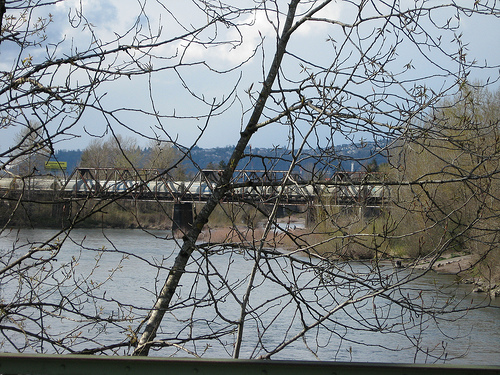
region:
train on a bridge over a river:
[0, 153, 392, 210]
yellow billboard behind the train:
[40, 159, 70, 176]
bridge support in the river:
[170, 201, 200, 236]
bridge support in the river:
[49, 198, 76, 228]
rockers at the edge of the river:
[471, 280, 498, 305]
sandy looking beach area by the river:
[413, 246, 471, 281]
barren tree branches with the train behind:
[11, 23, 358, 359]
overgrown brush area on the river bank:
[386, 96, 498, 291]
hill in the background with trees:
[13, 142, 396, 174]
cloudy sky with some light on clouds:
[1, 1, 488, 148]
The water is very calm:
[37, 213, 150, 321]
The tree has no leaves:
[12, 25, 462, 366]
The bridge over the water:
[18, 155, 410, 233]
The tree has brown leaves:
[374, 89, 498, 254]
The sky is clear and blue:
[19, 6, 232, 138]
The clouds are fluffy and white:
[81, 13, 311, 58]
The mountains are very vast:
[2, 130, 409, 187]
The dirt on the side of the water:
[418, 240, 497, 301]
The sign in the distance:
[31, 145, 82, 177]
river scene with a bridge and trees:
[7, 1, 494, 368]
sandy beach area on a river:
[411, 246, 478, 281]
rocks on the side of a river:
[457, 271, 497, 303]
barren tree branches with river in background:
[14, 1, 391, 341]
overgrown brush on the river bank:
[321, 85, 494, 300]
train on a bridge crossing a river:
[2, 167, 387, 208]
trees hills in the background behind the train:
[13, 142, 398, 181]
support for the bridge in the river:
[49, 196, 77, 227]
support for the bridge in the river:
[169, 199, 198, 236]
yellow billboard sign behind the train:
[44, 158, 67, 175]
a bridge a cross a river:
[5, 170, 212, 197]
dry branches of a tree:
[209, 216, 455, 352]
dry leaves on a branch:
[456, 32, 470, 55]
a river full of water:
[116, 230, 172, 268]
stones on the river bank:
[468, 274, 495, 299]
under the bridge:
[283, 201, 316, 223]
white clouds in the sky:
[210, 45, 259, 65]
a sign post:
[38, 160, 65, 172]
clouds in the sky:
[172, 13, 355, 68]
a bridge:
[35, 174, 410, 234]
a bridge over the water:
[18, 176, 453, 218]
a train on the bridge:
[1, 175, 421, 192]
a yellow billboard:
[46, 160, 76, 170]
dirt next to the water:
[414, 253, 469, 276]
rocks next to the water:
[456, 270, 496, 298]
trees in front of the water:
[24, 25, 492, 373]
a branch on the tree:
[117, 141, 192, 194]